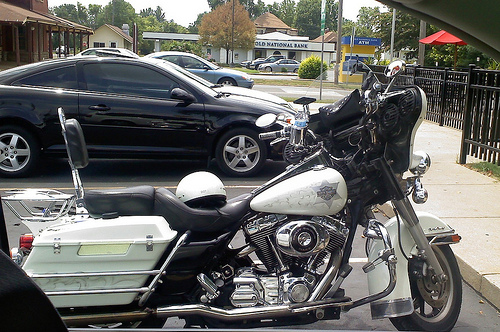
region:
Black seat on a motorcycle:
[42, 113, 164, 225]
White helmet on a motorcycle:
[154, 138, 248, 235]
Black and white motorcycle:
[46, 103, 486, 330]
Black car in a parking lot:
[6, 34, 315, 172]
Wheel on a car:
[212, 112, 289, 172]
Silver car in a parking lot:
[138, 47, 268, 89]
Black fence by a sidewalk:
[410, 55, 497, 137]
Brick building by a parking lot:
[13, 17, 122, 187]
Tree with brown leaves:
[200, 0, 277, 65]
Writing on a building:
[251, 28, 313, 55]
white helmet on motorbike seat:
[169, 156, 315, 238]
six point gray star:
[267, 171, 389, 232]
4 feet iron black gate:
[439, 54, 496, 164]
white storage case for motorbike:
[14, 194, 214, 320]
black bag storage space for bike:
[307, 82, 393, 135]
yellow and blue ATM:
[332, 29, 387, 96]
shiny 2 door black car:
[12, 52, 330, 179]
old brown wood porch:
[12, 2, 119, 66]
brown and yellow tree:
[193, 0, 272, 77]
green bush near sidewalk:
[294, 47, 334, 92]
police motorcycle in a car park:
[27, 96, 462, 323]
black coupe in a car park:
[5, 64, 289, 167]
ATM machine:
[343, 34, 375, 81]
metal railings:
[362, 63, 499, 145]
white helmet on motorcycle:
[177, 169, 226, 206]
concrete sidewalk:
[413, 132, 498, 260]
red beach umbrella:
[421, 26, 467, 56]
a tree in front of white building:
[205, 6, 251, 68]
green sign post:
[315, 1, 331, 54]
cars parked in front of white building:
[246, 54, 300, 76]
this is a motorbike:
[22, 125, 457, 325]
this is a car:
[91, 55, 226, 155]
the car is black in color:
[107, 110, 190, 146]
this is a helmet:
[186, 168, 212, 198]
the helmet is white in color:
[186, 173, 205, 185]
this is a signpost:
[313, 0, 328, 35]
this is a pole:
[333, 2, 345, 85]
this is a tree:
[206, 2, 251, 49]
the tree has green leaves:
[299, 6, 311, 18]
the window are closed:
[87, 60, 156, 90]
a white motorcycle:
[0, 37, 447, 322]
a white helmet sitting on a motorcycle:
[41, 44, 426, 274]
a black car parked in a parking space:
[0, 57, 302, 179]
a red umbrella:
[397, 17, 487, 62]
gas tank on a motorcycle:
[250, 143, 352, 228]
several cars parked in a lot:
[236, 46, 306, 80]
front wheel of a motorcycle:
[343, 203, 468, 323]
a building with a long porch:
[11, 14, 108, 79]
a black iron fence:
[337, 62, 485, 117]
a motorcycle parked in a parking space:
[0, 39, 460, 330]